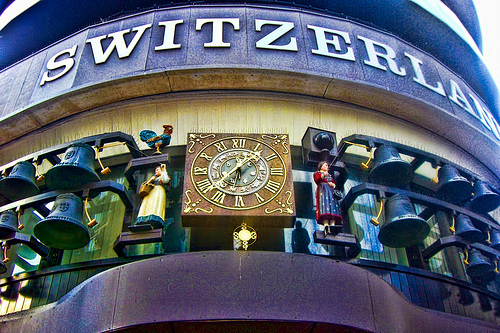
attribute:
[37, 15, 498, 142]
word — switzerland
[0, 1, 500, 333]
building — ornate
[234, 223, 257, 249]
pendulum — gold, yellow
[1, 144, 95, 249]
bells — black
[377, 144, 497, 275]
bells — black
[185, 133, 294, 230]
background — brown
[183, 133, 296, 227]
clock — brown, ornate, big, square, bronze colored, gold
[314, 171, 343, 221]
dress — white, red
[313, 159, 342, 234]
statue — white, woman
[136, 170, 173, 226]
dress — tan, blue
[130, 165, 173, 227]
figure — woman, white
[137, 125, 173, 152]
rooster — figure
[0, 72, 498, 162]
underside — lit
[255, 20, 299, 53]
letter — z, white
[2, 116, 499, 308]
facade — ornate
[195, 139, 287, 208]
roman numerals — gold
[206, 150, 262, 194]
hands — gold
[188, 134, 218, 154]
corner design — gold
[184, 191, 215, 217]
design — gold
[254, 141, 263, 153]
roman numeral — gold, one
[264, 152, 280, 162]
roman numeral — golden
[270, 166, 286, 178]
roman numeral — three, golden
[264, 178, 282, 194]
roman numeral — golden, four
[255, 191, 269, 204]
roman numeral — five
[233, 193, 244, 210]
roman numeral — six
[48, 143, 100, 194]
bell — blue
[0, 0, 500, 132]
background — blue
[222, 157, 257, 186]
center — grey